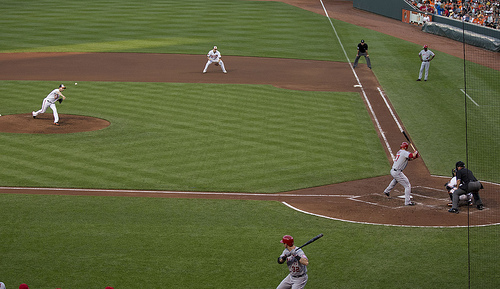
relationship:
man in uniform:
[383, 140, 420, 205] [384, 151, 414, 199]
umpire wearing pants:
[453, 160, 485, 216] [451, 182, 483, 206]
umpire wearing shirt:
[453, 160, 485, 216] [456, 168, 479, 184]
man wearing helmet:
[383, 140, 420, 205] [399, 142, 409, 149]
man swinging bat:
[383, 140, 420, 205] [403, 129, 420, 153]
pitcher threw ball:
[34, 87, 66, 125] [72, 82, 79, 86]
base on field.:
[351, 82, 365, 90] [3, 3, 499, 288]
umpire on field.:
[453, 160, 485, 216] [3, 3, 499, 288]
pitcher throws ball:
[34, 87, 66, 125] [72, 82, 79, 86]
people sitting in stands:
[477, 6, 488, 19] [351, 1, 499, 52]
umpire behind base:
[453, 160, 485, 216] [398, 193, 414, 201]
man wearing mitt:
[203, 46, 228, 75] [217, 64, 221, 67]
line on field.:
[320, 11, 420, 202] [3, 3, 499, 288]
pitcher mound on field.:
[3, 110, 108, 136] [3, 3, 499, 288]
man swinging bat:
[278, 234, 314, 285] [292, 232, 325, 257]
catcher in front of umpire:
[444, 168, 460, 200] [453, 160, 485, 216]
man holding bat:
[383, 140, 420, 205] [403, 129, 420, 153]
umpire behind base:
[357, 40, 374, 71] [351, 82, 365, 90]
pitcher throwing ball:
[34, 87, 66, 125] [72, 82, 79, 86]